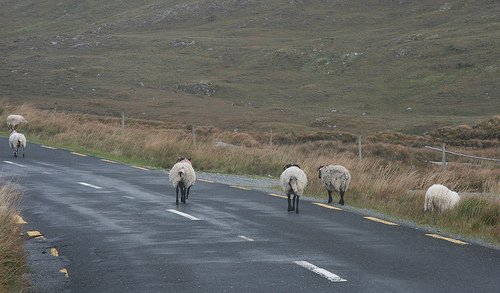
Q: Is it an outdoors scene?
A: Yes, it is outdoors.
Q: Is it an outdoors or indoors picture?
A: It is outdoors.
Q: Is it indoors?
A: No, it is outdoors.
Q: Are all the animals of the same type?
A: Yes, all the animals are sheep.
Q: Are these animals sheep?
A: Yes, all the animals are sheep.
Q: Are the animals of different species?
A: No, all the animals are sheep.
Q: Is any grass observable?
A: Yes, there is grass.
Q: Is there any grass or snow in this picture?
A: Yes, there is grass.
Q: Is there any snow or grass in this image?
A: Yes, there is grass.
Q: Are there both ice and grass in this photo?
A: No, there is grass but no ice.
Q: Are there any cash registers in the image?
A: No, there are no cash registers.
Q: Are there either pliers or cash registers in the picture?
A: No, there are no cash registers or pliers.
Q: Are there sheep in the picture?
A: Yes, there is a sheep.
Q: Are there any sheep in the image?
A: Yes, there is a sheep.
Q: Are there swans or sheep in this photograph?
A: Yes, there is a sheep.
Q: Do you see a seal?
A: No, there are no seals.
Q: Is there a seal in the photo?
A: No, there are no seals.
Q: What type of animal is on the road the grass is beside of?
A: The animal is a sheep.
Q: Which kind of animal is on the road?
A: The animal is a sheep.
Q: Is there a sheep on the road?
A: Yes, there is a sheep on the road.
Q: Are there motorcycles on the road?
A: No, there is a sheep on the road.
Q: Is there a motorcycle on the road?
A: No, there is a sheep on the road.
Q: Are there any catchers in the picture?
A: No, there are no catchers.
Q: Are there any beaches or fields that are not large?
A: No, there is a field but it is large.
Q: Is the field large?
A: Yes, the field is large.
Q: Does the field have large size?
A: Yes, the field is large.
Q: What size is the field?
A: The field is large.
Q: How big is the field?
A: The field is large.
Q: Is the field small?
A: No, the field is large.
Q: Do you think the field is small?
A: No, the field is large.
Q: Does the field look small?
A: No, the field is large.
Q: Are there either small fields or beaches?
A: No, there is a field but it is large.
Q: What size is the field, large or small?
A: The field is large.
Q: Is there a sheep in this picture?
A: Yes, there is a sheep.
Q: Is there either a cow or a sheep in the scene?
A: Yes, there is a sheep.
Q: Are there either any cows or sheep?
A: Yes, there is a sheep.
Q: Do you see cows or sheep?
A: Yes, there is a sheep.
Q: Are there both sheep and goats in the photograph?
A: No, there is a sheep but no goats.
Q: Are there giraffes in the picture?
A: No, there are no giraffes.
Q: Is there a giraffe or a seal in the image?
A: No, there are no giraffes or seals.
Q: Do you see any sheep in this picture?
A: Yes, there is a sheep.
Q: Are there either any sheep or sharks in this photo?
A: Yes, there is a sheep.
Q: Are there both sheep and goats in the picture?
A: No, there is a sheep but no goats.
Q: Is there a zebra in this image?
A: No, there are no zebras.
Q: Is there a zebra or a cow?
A: No, there are no zebras or cows.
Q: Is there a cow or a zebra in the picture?
A: No, there are no zebras or cows.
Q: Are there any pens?
A: No, there are no pens.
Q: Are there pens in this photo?
A: No, there are no pens.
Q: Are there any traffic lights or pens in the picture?
A: No, there are no pens or traffic lights.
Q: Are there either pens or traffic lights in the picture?
A: No, there are no pens or traffic lights.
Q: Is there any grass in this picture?
A: Yes, there is grass.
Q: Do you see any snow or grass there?
A: Yes, there is grass.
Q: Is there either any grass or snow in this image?
A: Yes, there is grass.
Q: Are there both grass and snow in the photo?
A: No, there is grass but no snow.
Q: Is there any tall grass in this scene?
A: Yes, there is tall grass.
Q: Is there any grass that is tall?
A: Yes, there is grass that is tall.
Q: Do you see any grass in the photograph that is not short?
A: Yes, there is tall grass.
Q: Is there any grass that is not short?
A: Yes, there is tall grass.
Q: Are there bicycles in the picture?
A: No, there are no bicycles.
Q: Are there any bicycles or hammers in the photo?
A: No, there are no bicycles or hammers.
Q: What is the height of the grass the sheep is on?
A: The grass is tall.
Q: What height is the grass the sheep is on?
A: The grass is tall.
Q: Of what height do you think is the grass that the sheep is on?
A: The grass is tall.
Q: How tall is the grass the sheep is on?
A: The grass is tall.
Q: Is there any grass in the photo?
A: Yes, there is grass.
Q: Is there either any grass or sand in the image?
A: Yes, there is grass.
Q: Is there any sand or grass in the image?
A: Yes, there is grass.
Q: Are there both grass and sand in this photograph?
A: No, there is grass but no sand.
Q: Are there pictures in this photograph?
A: No, there are no pictures.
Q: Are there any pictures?
A: No, there are no pictures.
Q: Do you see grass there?
A: Yes, there is grass.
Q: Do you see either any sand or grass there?
A: Yes, there is grass.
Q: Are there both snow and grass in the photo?
A: No, there is grass but no snow.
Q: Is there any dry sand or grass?
A: Yes, there is dry grass.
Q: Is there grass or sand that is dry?
A: Yes, the grass is dry.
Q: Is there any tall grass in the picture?
A: Yes, there is tall grass.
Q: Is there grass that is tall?
A: Yes, there is grass that is tall.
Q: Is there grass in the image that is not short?
A: Yes, there is tall grass.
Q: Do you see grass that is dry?
A: Yes, there is dry grass.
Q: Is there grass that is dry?
A: Yes, there is grass that is dry.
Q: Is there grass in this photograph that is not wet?
A: Yes, there is dry grass.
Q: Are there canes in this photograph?
A: No, there are no canes.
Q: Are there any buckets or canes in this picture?
A: No, there are no canes or buckets.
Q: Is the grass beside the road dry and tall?
A: Yes, the grass is dry and tall.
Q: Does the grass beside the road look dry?
A: Yes, the grass is dry.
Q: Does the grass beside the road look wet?
A: No, the grass is dry.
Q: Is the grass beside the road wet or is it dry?
A: The grass is dry.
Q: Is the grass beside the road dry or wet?
A: The grass is dry.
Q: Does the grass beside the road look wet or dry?
A: The grass is dry.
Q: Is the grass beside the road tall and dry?
A: Yes, the grass is tall and dry.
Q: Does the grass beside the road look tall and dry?
A: Yes, the grass is tall and dry.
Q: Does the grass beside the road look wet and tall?
A: No, the grass is tall but dry.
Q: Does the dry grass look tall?
A: Yes, the grass is tall.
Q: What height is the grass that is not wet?
A: The grass is tall.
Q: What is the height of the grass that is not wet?
A: The grass is tall.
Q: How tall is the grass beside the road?
A: The grass is tall.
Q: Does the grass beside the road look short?
A: No, the grass is tall.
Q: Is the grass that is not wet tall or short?
A: The grass is tall.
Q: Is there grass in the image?
A: Yes, there is grass.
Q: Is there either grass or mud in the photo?
A: Yes, there is grass.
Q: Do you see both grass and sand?
A: No, there is grass but no sand.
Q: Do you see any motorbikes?
A: No, there are no motorbikes.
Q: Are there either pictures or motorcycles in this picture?
A: No, there are no motorcycles or pictures.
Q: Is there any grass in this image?
A: Yes, there is grass.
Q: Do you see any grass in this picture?
A: Yes, there is grass.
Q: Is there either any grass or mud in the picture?
A: Yes, there is grass.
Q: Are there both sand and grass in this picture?
A: No, there is grass but no sand.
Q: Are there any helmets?
A: No, there are no helmets.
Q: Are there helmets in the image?
A: No, there are no helmets.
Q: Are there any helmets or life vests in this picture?
A: No, there are no helmets or life vests.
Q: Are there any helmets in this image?
A: No, there are no helmets.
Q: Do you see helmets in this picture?
A: No, there are no helmets.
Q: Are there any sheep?
A: Yes, there is a sheep.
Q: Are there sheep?
A: Yes, there is a sheep.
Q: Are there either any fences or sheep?
A: Yes, there is a sheep.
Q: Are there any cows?
A: No, there are no cows.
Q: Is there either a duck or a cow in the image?
A: No, there are no cows or ducks.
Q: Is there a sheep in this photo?
A: Yes, there is a sheep.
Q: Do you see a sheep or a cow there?
A: Yes, there is a sheep.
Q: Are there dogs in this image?
A: No, there are no dogs.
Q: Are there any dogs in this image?
A: No, there are no dogs.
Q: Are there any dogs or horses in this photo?
A: No, there are no dogs or horses.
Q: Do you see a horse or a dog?
A: No, there are no dogs or horses.